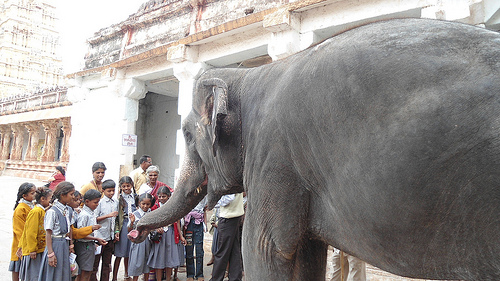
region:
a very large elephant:
[134, 19, 483, 274]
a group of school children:
[7, 147, 171, 279]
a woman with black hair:
[66, 157, 121, 199]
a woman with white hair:
[136, 160, 176, 199]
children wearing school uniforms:
[7, 176, 244, 278]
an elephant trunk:
[108, 163, 217, 265]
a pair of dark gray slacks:
[207, 214, 255, 279]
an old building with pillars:
[1, 13, 487, 274]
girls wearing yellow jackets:
[1, 171, 50, 278]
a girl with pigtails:
[110, 166, 145, 227]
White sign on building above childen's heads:
[116, 130, 146, 150]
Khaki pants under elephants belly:
[328, 244, 379, 279]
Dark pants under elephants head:
[210, 212, 248, 277]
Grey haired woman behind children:
[134, 164, 169, 198]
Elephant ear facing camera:
[186, 79, 239, 156]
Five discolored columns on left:
[1, 122, 77, 167]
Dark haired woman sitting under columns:
[43, 157, 70, 197]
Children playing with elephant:
[14, 172, 211, 273]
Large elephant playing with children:
[111, 7, 499, 274]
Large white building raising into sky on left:
[0, 0, 70, 97]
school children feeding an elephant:
[72, 15, 498, 273]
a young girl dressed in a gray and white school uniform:
[38, 181, 77, 279]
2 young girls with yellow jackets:
[13, 181, 55, 278]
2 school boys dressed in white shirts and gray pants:
[79, 176, 118, 279]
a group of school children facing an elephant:
[2, 157, 212, 279]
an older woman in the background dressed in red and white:
[130, 161, 171, 210]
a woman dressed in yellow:
[72, 155, 111, 205]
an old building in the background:
[0, 0, 214, 178]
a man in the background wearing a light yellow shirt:
[128, 153, 161, 201]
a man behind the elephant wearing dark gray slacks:
[211, 189, 246, 278]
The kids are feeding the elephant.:
[16, 151, 284, 278]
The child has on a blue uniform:
[47, 208, 74, 264]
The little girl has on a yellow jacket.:
[20, 209, 42, 256]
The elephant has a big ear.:
[197, 76, 233, 146]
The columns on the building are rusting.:
[11, 120, 68, 190]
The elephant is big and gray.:
[231, 58, 461, 248]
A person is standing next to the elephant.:
[206, 191, 283, 279]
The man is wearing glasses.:
[137, 151, 159, 179]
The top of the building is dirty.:
[69, 30, 249, 73]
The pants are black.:
[208, 216, 250, 266]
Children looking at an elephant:
[13, 146, 170, 276]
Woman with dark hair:
[78, 156, 120, 203]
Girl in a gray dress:
[35, 180, 99, 279]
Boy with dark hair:
[96, 177, 127, 272]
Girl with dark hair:
[12, 181, 39, 270]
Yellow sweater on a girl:
[6, 181, 68, 266]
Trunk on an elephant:
[128, 136, 233, 275]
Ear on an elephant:
[185, 78, 234, 126]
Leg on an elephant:
[231, 168, 308, 278]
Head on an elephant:
[159, 60, 288, 207]